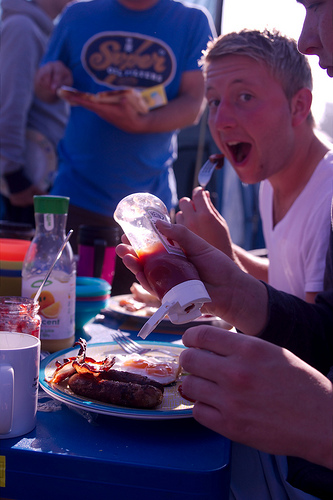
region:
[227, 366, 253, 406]
red spots on man's knuckles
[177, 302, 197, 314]
red ketchup on lid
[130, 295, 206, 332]
open lid on ketchup bottle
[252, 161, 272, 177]
small red spot on man's face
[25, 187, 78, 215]
green top on juice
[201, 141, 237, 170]
food at end of fork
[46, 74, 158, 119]
large slice of pizza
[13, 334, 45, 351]
lid of white mug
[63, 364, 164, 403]
large piece of brown sausage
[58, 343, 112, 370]
crispy strip of bacon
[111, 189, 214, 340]
bottle of heinz ketchup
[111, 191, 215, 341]
bottle ketchup in a person's hand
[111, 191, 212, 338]
person getting ready to pour ketchup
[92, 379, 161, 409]
well cooked sausage link on a plate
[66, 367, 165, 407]
two well cooked sausages on a plate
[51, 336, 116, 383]
pieces of crispy bacon on a plate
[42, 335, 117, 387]
crunchy curled pieces of bacon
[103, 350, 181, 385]
eggs on a plate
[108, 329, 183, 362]
silver fork on a plate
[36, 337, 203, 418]
breakfast meal on a plate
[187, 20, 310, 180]
the head of a man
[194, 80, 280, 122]
the eyes of a man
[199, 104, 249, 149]
the nose of a man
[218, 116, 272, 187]
the mouth of a man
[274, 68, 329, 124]
the ear of a man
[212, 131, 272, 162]
the teeth of a man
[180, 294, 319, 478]
the hand of a man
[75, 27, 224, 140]
the arm of a man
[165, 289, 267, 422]
the fingers of a man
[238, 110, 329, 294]
a man wearing a shirt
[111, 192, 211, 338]
a half a bottle of ketchup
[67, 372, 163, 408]
two brown sausage links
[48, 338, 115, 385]
strips of crispy bacon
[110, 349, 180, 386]
a runny fried egg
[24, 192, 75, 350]
a bottle of orange juice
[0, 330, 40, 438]
a white coffee mug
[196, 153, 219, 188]
the tip of a fork with food on it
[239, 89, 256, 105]
a blond guy's left eye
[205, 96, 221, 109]
a blonde guy's right eye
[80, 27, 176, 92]
logo on a shirt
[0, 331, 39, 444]
white coffee mug on a blue table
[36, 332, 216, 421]
bacon, sausage and egg breakfast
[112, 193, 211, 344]
plastic bottle of red ketchup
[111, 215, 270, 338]
right hand holding ketchup bottle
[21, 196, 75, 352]
clear plastic bottle of juice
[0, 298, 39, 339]
jar of red jelly or jam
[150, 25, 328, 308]
man with a white tee shirt and blond hair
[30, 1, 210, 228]
blue tee shirt with a logo on the front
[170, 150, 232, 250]
left hand holding a fork with a bite of food on it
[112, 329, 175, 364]
stainless steel fork on a white plate